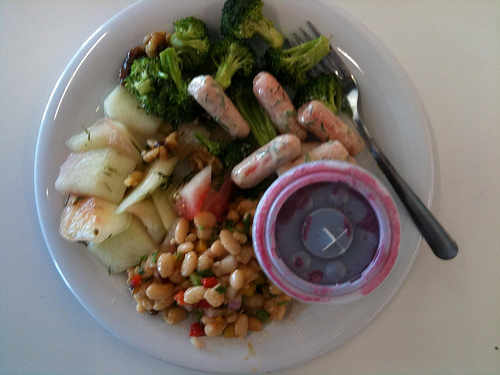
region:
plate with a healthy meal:
[32, 1, 437, 371]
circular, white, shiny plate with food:
[34, 0, 433, 372]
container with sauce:
[251, 160, 401, 307]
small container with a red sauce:
[253, 162, 400, 304]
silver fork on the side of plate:
[284, 20, 471, 258]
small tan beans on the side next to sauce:
[129, 196, 292, 346]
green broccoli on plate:
[118, 0, 344, 154]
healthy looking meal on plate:
[60, 1, 360, 340]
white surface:
[0, 0, 497, 373]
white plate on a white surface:
[33, 2, 435, 372]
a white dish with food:
[33, 0, 453, 367]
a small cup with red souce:
[249, 157, 404, 314]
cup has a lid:
[246, 154, 408, 319]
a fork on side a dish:
[283, 19, 459, 265]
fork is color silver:
[288, 17, 465, 276]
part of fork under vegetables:
[272, 15, 375, 130]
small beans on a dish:
[125, 202, 290, 349]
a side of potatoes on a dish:
[52, 81, 182, 273]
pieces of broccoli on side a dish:
[118, 0, 353, 129]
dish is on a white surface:
[3, 4, 498, 374]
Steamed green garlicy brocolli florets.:
[115, 13, 367, 148]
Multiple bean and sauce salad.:
[164, 183, 304, 370]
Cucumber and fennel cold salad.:
[67, 81, 191, 298]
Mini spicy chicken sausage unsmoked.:
[186, 67, 379, 184]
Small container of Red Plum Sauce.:
[255, 163, 407, 321]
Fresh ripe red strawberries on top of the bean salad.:
[147, 161, 260, 236]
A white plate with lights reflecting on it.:
[32, 0, 459, 371]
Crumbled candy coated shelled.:
[114, 28, 195, 86]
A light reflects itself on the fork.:
[344, 40, 384, 142]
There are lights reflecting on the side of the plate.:
[37, 13, 108, 356]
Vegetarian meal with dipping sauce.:
[31, 3, 402, 343]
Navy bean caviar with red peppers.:
[132, 201, 310, 334]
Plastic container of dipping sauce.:
[248, 164, 405, 302]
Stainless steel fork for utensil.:
[272, 19, 459, 266]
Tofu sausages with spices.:
[188, 70, 375, 187]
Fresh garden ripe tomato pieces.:
[171, 155, 241, 225]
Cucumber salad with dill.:
[61, 89, 199, 275]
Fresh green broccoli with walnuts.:
[125, 9, 352, 168]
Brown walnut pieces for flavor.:
[114, 26, 226, 193]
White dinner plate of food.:
[31, 8, 458, 365]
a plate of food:
[26, 7, 450, 323]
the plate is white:
[17, 0, 472, 337]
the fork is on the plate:
[272, 1, 469, 271]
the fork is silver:
[292, 15, 464, 275]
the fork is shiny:
[265, 2, 464, 269]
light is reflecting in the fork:
[336, 80, 370, 133]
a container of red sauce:
[242, 146, 392, 315]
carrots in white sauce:
[182, 72, 353, 158]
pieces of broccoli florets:
[118, 9, 333, 131]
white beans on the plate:
[114, 195, 305, 342]